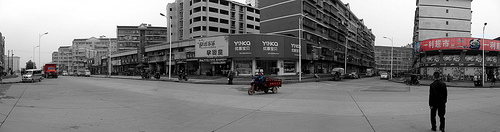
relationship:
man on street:
[253, 73, 261, 85] [8, 6, 488, 130]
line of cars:
[60, 61, 108, 82] [43, 54, 106, 83]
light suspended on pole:
[155, 6, 174, 25] [164, 7, 177, 89]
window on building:
[440, 14, 454, 29] [409, 0, 476, 55]